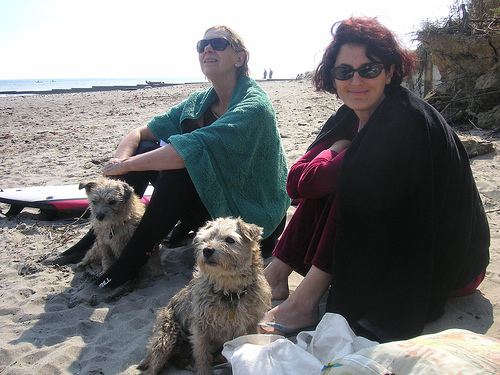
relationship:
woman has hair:
[174, 22, 251, 219] [226, 25, 251, 54]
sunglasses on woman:
[186, 41, 240, 57] [174, 22, 251, 219]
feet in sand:
[49, 252, 126, 300] [21, 243, 147, 354]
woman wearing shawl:
[174, 22, 251, 219] [210, 82, 283, 203]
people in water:
[25, 75, 63, 89] [10, 81, 138, 94]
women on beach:
[106, 57, 482, 259] [27, 74, 485, 304]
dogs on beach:
[58, 181, 279, 321] [27, 74, 485, 304]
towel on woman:
[358, 113, 452, 215] [303, 34, 460, 258]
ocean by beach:
[6, 41, 183, 84] [27, 74, 485, 304]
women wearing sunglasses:
[106, 57, 482, 259] [186, 41, 240, 57]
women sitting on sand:
[106, 57, 482, 259] [31, 96, 154, 135]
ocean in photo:
[6, 41, 183, 84] [31, 13, 475, 370]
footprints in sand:
[42, 119, 83, 141] [31, 96, 154, 135]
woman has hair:
[303, 34, 460, 258] [334, 31, 400, 59]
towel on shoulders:
[250, 330, 380, 366] [227, 88, 262, 139]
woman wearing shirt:
[303, 34, 460, 258] [285, 153, 346, 208]